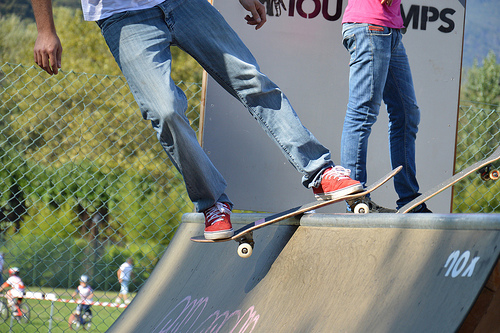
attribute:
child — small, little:
[70, 274, 95, 323]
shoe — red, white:
[204, 201, 235, 240]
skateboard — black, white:
[190, 165, 403, 258]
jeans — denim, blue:
[95, 0, 335, 212]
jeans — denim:
[342, 22, 426, 212]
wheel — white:
[238, 243, 252, 258]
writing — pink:
[152, 295, 259, 333]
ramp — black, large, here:
[105, 213, 500, 333]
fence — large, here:
[2, 233, 168, 292]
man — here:
[116, 258, 133, 307]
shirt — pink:
[341, 0, 405, 29]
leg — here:
[96, 20, 235, 239]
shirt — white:
[119, 262, 133, 281]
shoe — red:
[313, 166, 363, 201]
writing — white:
[444, 250, 480, 278]